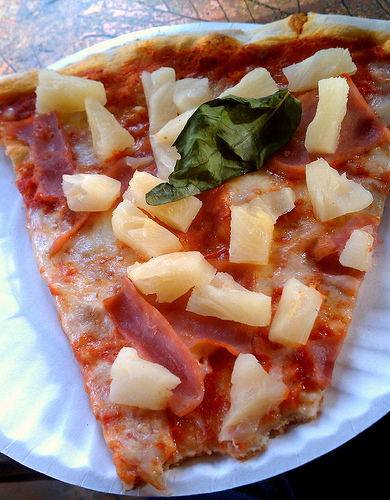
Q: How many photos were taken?
A: 30.